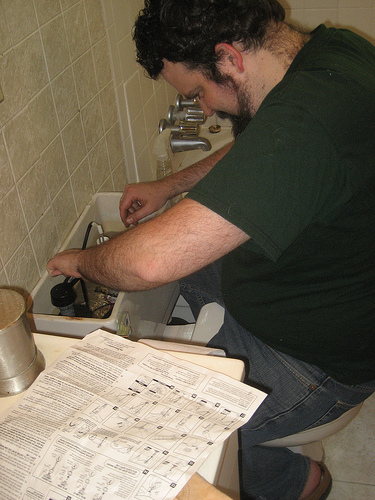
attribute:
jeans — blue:
[176, 255, 372, 498]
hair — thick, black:
[132, 2, 286, 83]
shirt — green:
[120, 21, 373, 354]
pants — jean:
[178, 256, 373, 497]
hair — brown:
[125, 4, 287, 80]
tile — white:
[322, 392, 373, 482]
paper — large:
[2, 328, 267, 494]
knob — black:
[38, 278, 96, 318]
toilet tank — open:
[14, 186, 189, 355]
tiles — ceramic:
[0, 0, 373, 300]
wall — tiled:
[5, 5, 121, 185]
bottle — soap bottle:
[154, 128, 176, 180]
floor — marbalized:
[313, 409, 370, 482]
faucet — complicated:
[103, 66, 256, 194]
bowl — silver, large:
[0, 286, 41, 393]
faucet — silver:
[159, 93, 210, 150]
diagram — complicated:
[1, 328, 269, 498]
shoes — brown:
[307, 458, 331, 499]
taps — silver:
[159, 115, 177, 129]